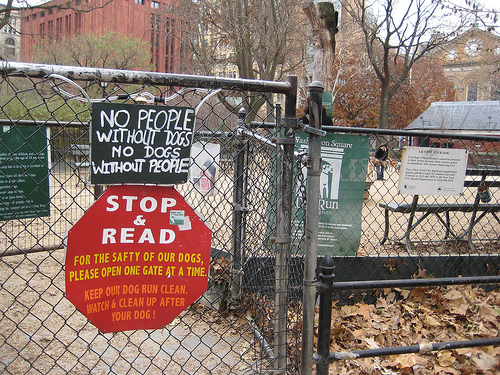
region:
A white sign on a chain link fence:
[396, 146, 466, 199]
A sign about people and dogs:
[89, 101, 192, 186]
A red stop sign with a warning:
[61, 188, 208, 332]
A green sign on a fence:
[271, 126, 371, 258]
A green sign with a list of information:
[0, 124, 52, 216]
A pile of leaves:
[250, 284, 498, 374]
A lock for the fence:
[279, 111, 328, 141]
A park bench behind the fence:
[376, 165, 499, 247]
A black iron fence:
[312, 251, 499, 369]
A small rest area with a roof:
[407, 99, 499, 171]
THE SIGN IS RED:
[57, 179, 223, 344]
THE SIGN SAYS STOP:
[98, 191, 179, 218]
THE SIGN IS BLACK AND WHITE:
[83, 95, 205, 180]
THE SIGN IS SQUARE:
[256, 120, 371, 277]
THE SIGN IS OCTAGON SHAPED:
[59, 183, 220, 340]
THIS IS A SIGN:
[51, 180, 224, 345]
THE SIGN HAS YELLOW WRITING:
[63, 248, 209, 286]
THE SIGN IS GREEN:
[258, 121, 378, 283]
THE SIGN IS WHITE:
[391, 140, 476, 203]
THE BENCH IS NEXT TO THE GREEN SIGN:
[380, 140, 499, 248]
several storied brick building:
[21, 1, 196, 109]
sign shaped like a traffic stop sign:
[63, 183, 211, 336]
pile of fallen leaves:
[251, 268, 498, 373]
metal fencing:
[314, 253, 499, 373]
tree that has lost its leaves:
[336, 1, 472, 151]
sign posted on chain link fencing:
[397, 145, 465, 199]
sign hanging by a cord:
[45, 73, 223, 186]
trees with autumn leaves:
[333, 18, 457, 133]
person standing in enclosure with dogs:
[368, 141, 399, 181]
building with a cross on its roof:
[406, 3, 498, 171]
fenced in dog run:
[4, 3, 491, 369]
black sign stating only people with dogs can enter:
[81, 99, 195, 190]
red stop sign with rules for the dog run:
[64, 178, 216, 333]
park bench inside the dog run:
[375, 163, 498, 247]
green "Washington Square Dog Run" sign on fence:
[268, 131, 367, 264]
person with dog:
[367, 137, 399, 182]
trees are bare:
[179, 7, 429, 143]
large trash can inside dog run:
[187, 137, 224, 199]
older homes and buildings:
[6, 11, 498, 105]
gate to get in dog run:
[2, 54, 324, 374]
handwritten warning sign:
[90, 102, 189, 183]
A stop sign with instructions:
[69, 188, 208, 329]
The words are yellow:
[70, 254, 92, 266]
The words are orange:
[85, 289, 105, 301]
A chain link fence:
[2, 64, 283, 374]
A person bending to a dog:
[372, 138, 387, 180]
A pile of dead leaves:
[337, 292, 480, 349]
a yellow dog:
[385, 158, 400, 174]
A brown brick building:
[415, 18, 499, 103]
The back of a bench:
[467, 168, 496, 241]